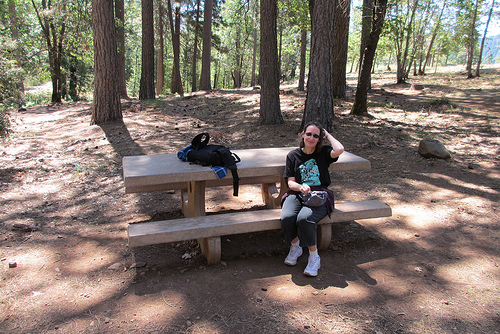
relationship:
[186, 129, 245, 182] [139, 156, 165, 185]
backpack on table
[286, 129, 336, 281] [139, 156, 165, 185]
woman at table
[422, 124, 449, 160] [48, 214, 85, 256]
rock on ground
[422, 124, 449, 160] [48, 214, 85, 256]
rock near ground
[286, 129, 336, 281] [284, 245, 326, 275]
woman wearing shoes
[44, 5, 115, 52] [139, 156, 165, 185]
trees next to table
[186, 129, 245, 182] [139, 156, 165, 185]
backpack on top of table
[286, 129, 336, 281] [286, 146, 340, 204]
woman wearing shirt